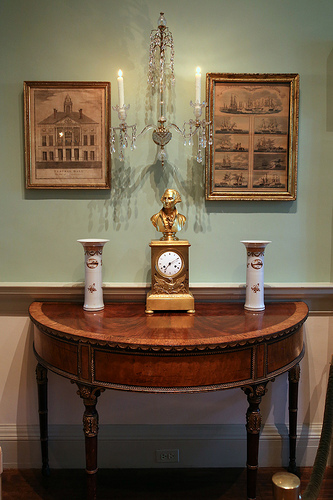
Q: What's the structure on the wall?
A: Chandelier.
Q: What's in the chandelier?
A: Candles.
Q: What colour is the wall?
A: Mint.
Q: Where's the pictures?
A: On wall.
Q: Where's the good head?
A: Above Clock.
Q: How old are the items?
A: Antique.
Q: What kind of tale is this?
A: Side table.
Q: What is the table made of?
A: Wood.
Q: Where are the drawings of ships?
A: In the framed picture.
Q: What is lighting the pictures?
A: Two candles.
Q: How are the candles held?
A: In the candle holder.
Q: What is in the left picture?
A: A building.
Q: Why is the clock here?
A: To show time.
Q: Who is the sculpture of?
A: George Washington.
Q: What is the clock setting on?
A: A wood table.